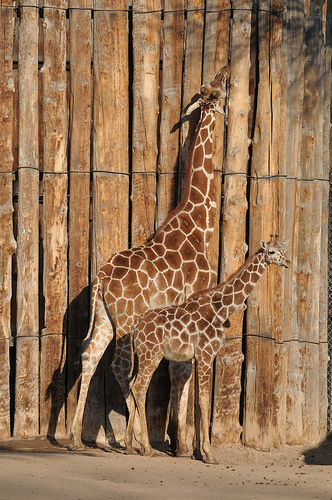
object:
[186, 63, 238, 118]
giraffe's head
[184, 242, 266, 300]
hair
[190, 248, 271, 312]
neck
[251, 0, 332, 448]
wood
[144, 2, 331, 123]
shade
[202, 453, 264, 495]
snow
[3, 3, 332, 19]
wire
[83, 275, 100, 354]
tail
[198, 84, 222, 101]
horns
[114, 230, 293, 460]
baby giraffe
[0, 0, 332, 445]
fence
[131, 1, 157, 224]
logs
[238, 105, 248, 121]
knobs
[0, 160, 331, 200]
seam fence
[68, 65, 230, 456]
adult giraffe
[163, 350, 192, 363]
belly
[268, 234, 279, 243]
horns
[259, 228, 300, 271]
head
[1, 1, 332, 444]
wall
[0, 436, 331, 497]
dirt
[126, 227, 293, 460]
hair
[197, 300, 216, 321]
spots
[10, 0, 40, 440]
log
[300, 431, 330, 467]
shadow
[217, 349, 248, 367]
knobs